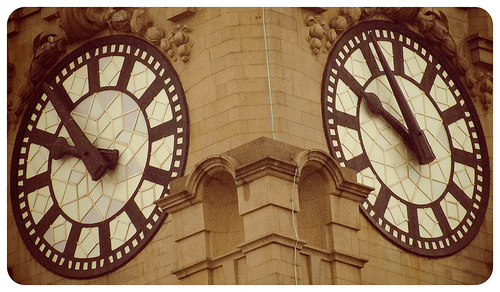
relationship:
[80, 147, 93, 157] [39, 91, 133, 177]
pin holding hands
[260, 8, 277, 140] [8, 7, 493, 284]
cable hanging on wall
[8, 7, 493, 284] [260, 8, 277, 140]
wall holding cable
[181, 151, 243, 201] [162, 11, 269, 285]
arch on the wall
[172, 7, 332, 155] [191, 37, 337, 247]
bricks on wall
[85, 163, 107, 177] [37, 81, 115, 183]
lower end on hands